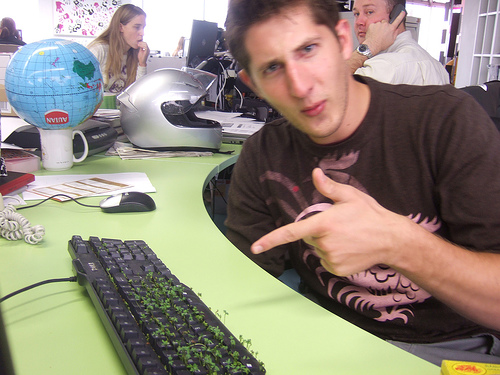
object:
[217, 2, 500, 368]
man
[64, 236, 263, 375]
keyboard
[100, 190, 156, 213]
mouse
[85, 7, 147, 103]
woman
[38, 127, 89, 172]
mug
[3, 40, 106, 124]
globe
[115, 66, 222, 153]
helmet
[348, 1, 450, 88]
man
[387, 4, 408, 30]
phone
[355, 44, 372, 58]
watch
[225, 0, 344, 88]
hair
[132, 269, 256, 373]
grass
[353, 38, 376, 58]
wrist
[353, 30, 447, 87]
shirt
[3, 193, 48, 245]
cord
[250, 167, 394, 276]
hand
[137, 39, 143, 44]
mouth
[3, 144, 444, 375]
desk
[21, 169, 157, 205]
paper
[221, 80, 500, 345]
shirt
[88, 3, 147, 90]
hair